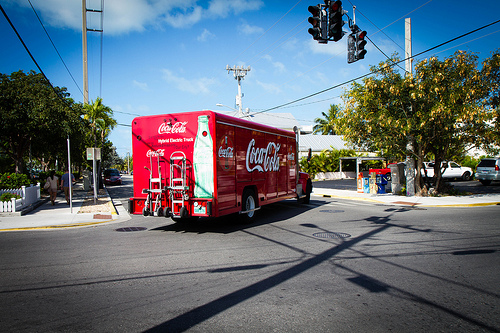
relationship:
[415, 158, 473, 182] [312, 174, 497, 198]
truck in parking lot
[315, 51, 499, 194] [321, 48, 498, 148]
tree has flowers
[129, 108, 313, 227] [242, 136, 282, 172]
truck has letters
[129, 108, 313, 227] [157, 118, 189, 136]
truck has letters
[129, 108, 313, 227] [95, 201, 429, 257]
truck at intersection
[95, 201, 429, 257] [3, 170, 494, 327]
intersection on street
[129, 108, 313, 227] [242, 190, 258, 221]
truck has wheel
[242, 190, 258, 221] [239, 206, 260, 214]
wheel has guard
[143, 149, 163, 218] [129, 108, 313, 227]
dolly on truck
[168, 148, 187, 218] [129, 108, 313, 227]
dolly on truck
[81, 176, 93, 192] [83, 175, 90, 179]
garbage can has lid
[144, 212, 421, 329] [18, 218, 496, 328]
shadow on ground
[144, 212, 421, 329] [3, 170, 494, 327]
shadow on road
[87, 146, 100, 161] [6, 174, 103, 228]
sign on sidewalk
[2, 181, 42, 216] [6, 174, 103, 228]
fence by sidewalk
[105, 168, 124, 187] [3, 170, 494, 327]
car on street